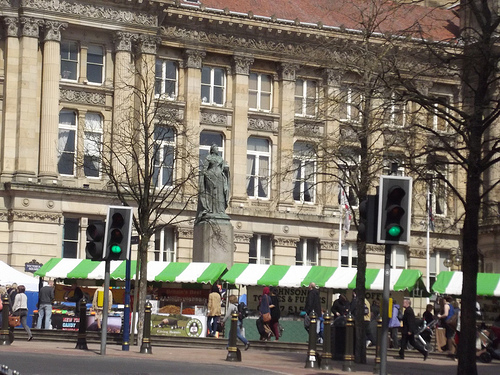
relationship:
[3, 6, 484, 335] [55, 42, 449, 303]
building with windows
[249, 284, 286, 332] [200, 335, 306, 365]
people walking down sidewalk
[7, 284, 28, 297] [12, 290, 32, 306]
woman in shirt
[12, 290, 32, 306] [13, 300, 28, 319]
shirt and pants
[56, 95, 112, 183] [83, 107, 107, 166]
window has curtain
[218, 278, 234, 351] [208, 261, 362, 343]
pole in front of business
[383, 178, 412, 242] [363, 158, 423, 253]
traffic lights with frame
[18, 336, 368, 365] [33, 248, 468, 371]
steps in front of flea market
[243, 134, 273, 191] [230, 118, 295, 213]
curtains inside windows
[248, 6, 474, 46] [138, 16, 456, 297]
roof on building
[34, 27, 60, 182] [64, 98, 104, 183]
columns on side of window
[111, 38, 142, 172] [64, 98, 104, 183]
columns on side of window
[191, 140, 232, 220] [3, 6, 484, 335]
statue by building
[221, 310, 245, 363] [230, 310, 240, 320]
pole with trim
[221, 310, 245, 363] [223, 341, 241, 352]
pole with trim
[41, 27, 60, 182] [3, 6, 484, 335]
columns on building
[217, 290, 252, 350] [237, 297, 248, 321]
woman wearing backpack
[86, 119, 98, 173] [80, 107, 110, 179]
curtain behind window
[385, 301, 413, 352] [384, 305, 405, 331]
woman wearing coat